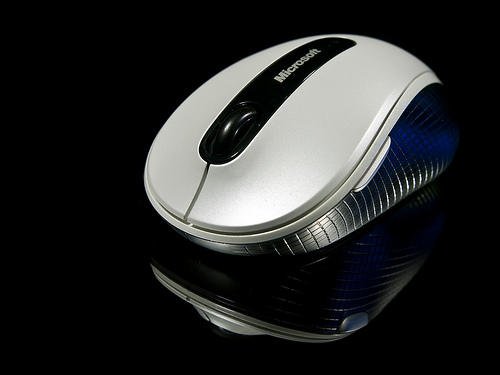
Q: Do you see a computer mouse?
A: Yes, there is a computer mouse.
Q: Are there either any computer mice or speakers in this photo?
A: Yes, there is a computer mouse.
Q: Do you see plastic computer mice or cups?
A: Yes, there is a plastic computer mouse.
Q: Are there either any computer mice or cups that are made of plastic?
A: Yes, the computer mouse is made of plastic.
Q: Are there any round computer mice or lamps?
A: Yes, there is a round computer mouse.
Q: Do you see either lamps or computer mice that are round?
A: Yes, the computer mouse is round.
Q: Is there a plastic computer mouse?
A: Yes, there is a computer mouse that is made of plastic.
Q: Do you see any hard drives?
A: No, there are no hard drives.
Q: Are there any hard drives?
A: No, there are no hard drives.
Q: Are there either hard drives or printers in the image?
A: No, there are no hard drives or printers.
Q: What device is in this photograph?
A: The device is a computer mouse.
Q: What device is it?
A: The device is a computer mouse.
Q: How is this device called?
A: This is a computer mouse.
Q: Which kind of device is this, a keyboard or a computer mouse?
A: This is a computer mouse.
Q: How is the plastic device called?
A: The device is a computer mouse.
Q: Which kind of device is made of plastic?
A: The device is a computer mouse.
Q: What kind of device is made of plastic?
A: The device is a computer mouse.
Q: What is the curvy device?
A: The device is a computer mouse.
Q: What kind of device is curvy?
A: The device is a computer mouse.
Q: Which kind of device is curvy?
A: The device is a computer mouse.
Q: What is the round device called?
A: The device is a computer mouse.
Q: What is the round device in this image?
A: The device is a computer mouse.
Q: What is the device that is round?
A: The device is a computer mouse.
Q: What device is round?
A: The device is a computer mouse.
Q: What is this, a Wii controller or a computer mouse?
A: This is a computer mouse.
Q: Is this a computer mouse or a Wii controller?
A: This is a computer mouse.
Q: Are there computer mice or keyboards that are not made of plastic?
A: No, there is a computer mouse but it is made of plastic.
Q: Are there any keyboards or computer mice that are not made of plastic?
A: No, there is a computer mouse but it is made of plastic.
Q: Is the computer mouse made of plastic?
A: Yes, the computer mouse is made of plastic.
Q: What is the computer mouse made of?
A: The computer mouse is made of plastic.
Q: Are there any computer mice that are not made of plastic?
A: No, there is a computer mouse but it is made of plastic.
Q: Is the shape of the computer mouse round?
A: Yes, the computer mouse is round.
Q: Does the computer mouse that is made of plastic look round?
A: Yes, the mouse is round.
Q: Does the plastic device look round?
A: Yes, the mouse is round.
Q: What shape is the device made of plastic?
A: The computer mouse is round.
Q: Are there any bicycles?
A: No, there are no bicycles.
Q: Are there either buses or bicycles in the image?
A: No, there are no bicycles or buses.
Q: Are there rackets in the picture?
A: No, there are no rackets.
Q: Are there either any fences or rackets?
A: No, there are no rackets or fences.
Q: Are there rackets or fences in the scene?
A: No, there are no rackets or fences.